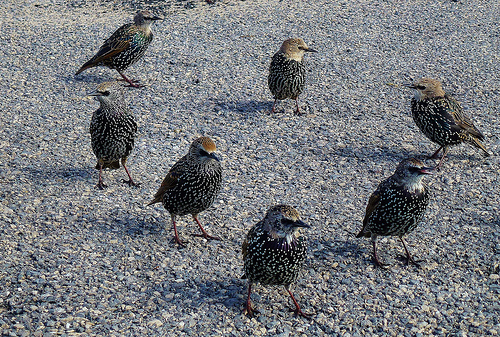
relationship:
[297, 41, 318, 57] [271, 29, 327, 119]
black beak bird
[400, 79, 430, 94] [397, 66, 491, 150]
black beak bird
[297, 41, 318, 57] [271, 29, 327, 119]
black eye bird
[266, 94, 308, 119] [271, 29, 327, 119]
claws on bird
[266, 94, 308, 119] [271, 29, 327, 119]
legs of bird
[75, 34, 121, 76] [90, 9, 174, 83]
wing of bird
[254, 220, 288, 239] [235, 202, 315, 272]
white feathers on bird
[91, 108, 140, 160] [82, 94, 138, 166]
multicolored feathered bird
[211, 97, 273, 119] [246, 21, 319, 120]
shadow of bird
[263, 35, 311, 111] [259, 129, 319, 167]
bird on pebbles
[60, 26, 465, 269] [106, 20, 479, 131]
group of little birds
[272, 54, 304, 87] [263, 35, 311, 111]
red legs bird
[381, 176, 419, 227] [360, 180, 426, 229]
white speckled bird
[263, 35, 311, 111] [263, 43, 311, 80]
bird spot on bird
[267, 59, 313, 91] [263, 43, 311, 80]
feathers on bird's throat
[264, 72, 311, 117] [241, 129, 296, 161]
black feet on gravel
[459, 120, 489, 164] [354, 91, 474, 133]
long tail of bird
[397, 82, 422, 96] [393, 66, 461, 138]
sharp black beak of bird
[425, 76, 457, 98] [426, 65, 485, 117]
brown and white feathers of bird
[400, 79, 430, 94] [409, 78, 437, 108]
black eye on birds face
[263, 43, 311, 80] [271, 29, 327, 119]
bird standing on pavement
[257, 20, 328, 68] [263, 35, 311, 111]
head of bird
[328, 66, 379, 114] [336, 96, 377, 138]
pavement on road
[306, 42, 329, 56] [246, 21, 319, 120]
beak of bird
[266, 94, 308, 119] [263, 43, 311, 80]
legs of bird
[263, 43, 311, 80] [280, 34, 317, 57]
bird with brown head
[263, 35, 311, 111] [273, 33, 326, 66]
bird looking right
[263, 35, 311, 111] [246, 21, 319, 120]
bird black bird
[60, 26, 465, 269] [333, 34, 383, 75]
seven birds on pavement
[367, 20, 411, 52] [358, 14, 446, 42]
rocks on ground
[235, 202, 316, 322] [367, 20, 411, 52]
bird standing on rocks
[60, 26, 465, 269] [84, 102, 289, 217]
flock on pavement